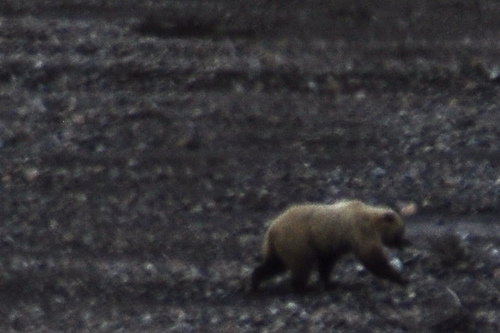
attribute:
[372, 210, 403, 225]
ear — small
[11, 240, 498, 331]
path — small, grey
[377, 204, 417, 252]
head — brown, black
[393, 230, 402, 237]
eye — small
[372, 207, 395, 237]
ear — brown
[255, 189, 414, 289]
bear — brown, walking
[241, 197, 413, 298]
bear — brown, walking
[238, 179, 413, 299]
bear — brown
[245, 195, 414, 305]
bear — brown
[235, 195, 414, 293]
bear — walking, small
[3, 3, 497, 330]
ground — dirt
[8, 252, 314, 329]
ground — white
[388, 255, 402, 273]
rock — small, white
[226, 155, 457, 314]
bear — brown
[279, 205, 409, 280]
bear — walking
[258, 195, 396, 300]
bear — brown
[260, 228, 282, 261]
bear tail — small, brown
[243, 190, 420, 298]
bear — brown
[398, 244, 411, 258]
mouth — open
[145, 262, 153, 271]
rock — small, white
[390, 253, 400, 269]
rock — small, white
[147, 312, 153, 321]
rock — small, white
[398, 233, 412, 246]
muzzle — black